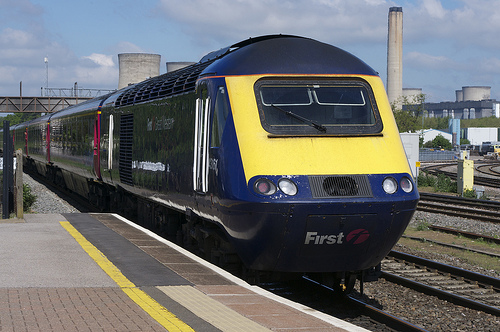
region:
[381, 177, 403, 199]
headlights are clear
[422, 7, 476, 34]
clouds in the sky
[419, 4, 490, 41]
the clouds are white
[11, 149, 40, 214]
a pole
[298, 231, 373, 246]
a logo on the train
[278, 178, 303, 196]
the headlight on the train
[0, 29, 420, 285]
Black train on train tracks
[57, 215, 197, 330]
Yellow painted stripe on the ground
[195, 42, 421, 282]
Blue and yellow front of a train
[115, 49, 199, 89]
Top of two smoke stacks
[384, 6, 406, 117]
Tall slim smoke stack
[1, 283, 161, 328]
Brick layed on the ground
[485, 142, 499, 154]
Yellow vehicle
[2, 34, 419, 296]
Train operating on train tracks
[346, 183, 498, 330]
Rows of metal train tracks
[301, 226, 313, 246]
letter f on train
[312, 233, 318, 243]
letter i on train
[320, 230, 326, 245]
letter r on train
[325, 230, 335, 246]
letter s on train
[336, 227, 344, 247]
letter t on train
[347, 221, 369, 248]
red symbol on train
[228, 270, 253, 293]
white strip on platform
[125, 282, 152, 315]
yellow strip on platfom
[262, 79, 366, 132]
big window on train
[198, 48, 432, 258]
large blue and yellow commuter train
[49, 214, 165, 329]
yellow painted line on a platform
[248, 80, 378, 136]
front window of a train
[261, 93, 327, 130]
windshield wiper on a train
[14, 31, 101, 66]
white clouds in the sky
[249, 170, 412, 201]
headlights on the front of train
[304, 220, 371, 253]
letters on a train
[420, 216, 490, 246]
weeds next to train tracks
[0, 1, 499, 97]
clouds in daytime sky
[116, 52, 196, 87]
cooling towers of power plant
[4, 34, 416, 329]
commuter train on tracks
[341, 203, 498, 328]
rails of train tracks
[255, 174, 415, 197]
four lights on train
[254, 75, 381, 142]
wiper on train windshield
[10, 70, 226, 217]
reflection on side of train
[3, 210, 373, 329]
white line on edge of platform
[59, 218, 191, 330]
yellow line on platform